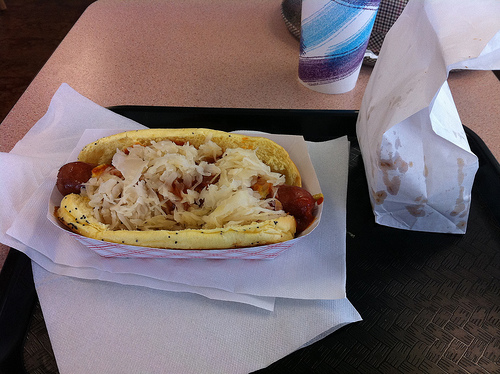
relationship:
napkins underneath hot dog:
[52, 245, 317, 356] [81, 148, 291, 223]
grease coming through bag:
[384, 160, 463, 214] [370, 107, 471, 263]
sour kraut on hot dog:
[102, 153, 263, 216] [56, 116, 310, 347]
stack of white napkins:
[34, 247, 353, 374] [33, 270, 360, 372]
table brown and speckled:
[86, 75, 289, 104] [22, 99, 58, 141]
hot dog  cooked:
[66, 180, 290, 213] [102, 159, 164, 203]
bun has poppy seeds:
[42, 85, 341, 304] [122, 231, 263, 251]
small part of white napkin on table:
[89, 340, 106, 363] [20, 134, 494, 374]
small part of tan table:
[168, 104, 208, 114] [21, 64, 331, 125]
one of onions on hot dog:
[123, 157, 133, 168] [62, 141, 305, 234]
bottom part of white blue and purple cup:
[303, 51, 343, 86] [318, 99, 332, 106]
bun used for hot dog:
[54, 125, 300, 250] [114, 172, 244, 196]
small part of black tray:
[368, 284, 390, 309] [242, 211, 475, 374]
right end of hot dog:
[274, 190, 317, 219] [73, 154, 283, 205]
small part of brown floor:
[13, 50, 23, 52] [16, 100, 33, 101]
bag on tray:
[354, 0, 499, 236] [374, 234, 468, 308]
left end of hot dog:
[44, 166, 87, 196] [44, 127, 225, 317]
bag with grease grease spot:
[381, 91, 473, 251] [379, 168, 399, 197]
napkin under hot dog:
[77, 265, 313, 296] [91, 139, 282, 249]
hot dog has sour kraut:
[53, 126, 318, 249] [74, 139, 281, 234]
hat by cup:
[279, 3, 405, 67] [297, 0, 381, 94]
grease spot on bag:
[377, 152, 411, 175] [354, 0, 497, 230]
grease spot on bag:
[381, 171, 401, 193] [354, 0, 497, 230]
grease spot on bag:
[450, 150, 469, 190] [354, 0, 497, 230]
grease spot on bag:
[454, 214, 465, 230] [354, 0, 497, 230]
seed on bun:
[271, 219, 278, 229] [60, 128, 301, 247]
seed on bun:
[171, 237, 181, 245] [60, 128, 301, 247]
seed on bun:
[164, 231, 173, 241] [60, 128, 301, 247]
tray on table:
[2, 93, 496, 370] [46, 1, 300, 110]